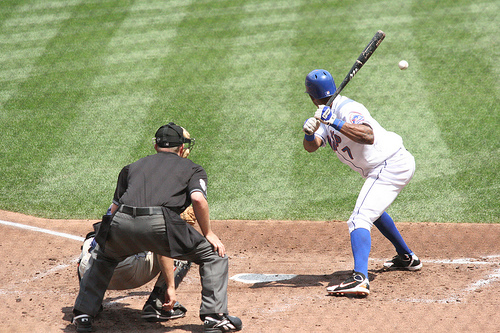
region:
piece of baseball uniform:
[326, 265, 373, 299]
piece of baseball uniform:
[376, 248, 430, 271]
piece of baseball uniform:
[345, 223, 370, 275]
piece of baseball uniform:
[366, 210, 414, 252]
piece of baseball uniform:
[343, 140, 413, 230]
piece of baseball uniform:
[303, 94, 402, 166]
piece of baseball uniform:
[296, 115, 323, 135]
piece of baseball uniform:
[313, 104, 343, 131]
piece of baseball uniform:
[302, 65, 340, 101]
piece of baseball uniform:
[151, 116, 198, 160]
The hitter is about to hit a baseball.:
[300, 30, 420, 298]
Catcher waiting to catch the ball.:
[67, 30, 421, 328]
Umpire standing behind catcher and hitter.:
[70, 31, 422, 327]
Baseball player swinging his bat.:
[302, 29, 422, 298]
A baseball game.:
[2, 4, 497, 331]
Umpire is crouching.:
[67, 120, 241, 331]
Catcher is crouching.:
[75, 201, 199, 320]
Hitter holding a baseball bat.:
[301, 29, 423, 297]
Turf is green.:
[0, 1, 499, 222]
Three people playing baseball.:
[72, 29, 422, 332]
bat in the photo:
[301, 15, 408, 122]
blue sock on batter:
[325, 213, 378, 275]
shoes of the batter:
[308, 253, 385, 313]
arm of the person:
[324, 110, 380, 145]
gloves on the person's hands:
[288, 103, 340, 144]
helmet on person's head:
[292, 55, 362, 117]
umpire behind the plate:
[104, 119, 212, 251]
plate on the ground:
[215, 250, 315, 314]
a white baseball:
[395, 59, 408, 71]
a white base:
[230, 270, 297, 287]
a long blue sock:
[352, 226, 373, 276]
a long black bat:
[318, 25, 388, 132]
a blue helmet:
[302, 67, 339, 102]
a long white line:
[2, 217, 89, 251]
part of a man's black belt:
[117, 204, 163, 216]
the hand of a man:
[203, 226, 228, 259]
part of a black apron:
[155, 205, 204, 262]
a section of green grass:
[0, 0, 499, 227]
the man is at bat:
[286, 22, 498, 329]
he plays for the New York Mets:
[283, 22, 493, 330]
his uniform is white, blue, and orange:
[279, 25, 479, 331]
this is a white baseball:
[391, 51, 418, 81]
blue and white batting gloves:
[287, 90, 371, 163]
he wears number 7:
[321, 135, 403, 186]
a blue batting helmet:
[286, 58, 365, 110]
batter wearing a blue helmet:
[303, 68, 423, 297]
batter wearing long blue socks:
[295, 68, 421, 298]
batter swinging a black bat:
[289, 68, 424, 298]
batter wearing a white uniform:
[296, 67, 422, 293]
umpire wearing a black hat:
[73, 122, 242, 329]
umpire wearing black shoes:
[73, 121, 245, 328]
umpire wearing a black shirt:
[69, 122, 244, 329]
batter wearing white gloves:
[300, 70, 421, 297]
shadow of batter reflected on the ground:
[249, 270, 376, 300]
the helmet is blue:
[301, 65, 341, 112]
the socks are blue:
[336, 212, 428, 277]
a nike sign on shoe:
[336, 271, 360, 290]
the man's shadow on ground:
[256, 253, 338, 298]